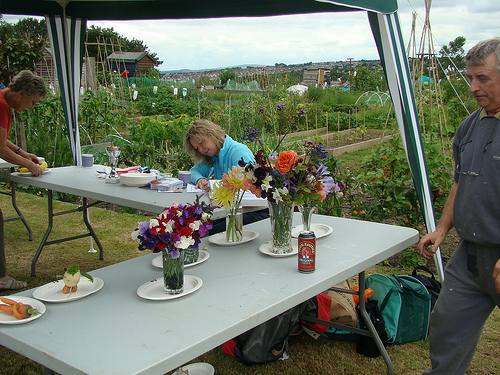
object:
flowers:
[268, 148, 301, 175]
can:
[295, 231, 318, 274]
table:
[0, 211, 418, 375]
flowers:
[135, 220, 149, 236]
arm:
[437, 125, 463, 239]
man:
[414, 37, 499, 375]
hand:
[417, 228, 445, 260]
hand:
[484, 257, 499, 293]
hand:
[194, 178, 211, 190]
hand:
[25, 161, 44, 177]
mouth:
[471, 95, 492, 104]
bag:
[365, 272, 433, 345]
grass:
[0, 189, 499, 374]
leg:
[420, 244, 495, 374]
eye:
[477, 74, 491, 83]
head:
[178, 119, 223, 158]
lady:
[184, 119, 258, 188]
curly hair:
[182, 116, 227, 163]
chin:
[474, 99, 498, 110]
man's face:
[461, 39, 499, 116]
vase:
[160, 250, 183, 290]